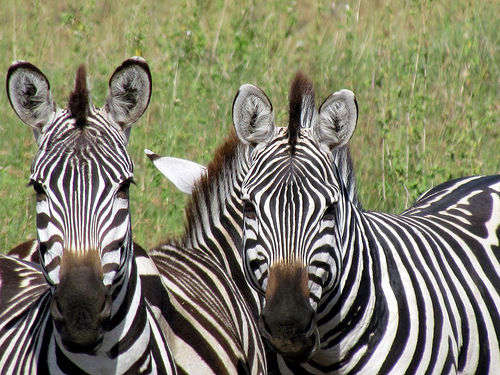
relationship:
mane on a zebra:
[275, 62, 336, 152] [228, 84, 497, 373]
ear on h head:
[228, 80, 282, 147] [228, 76, 371, 363]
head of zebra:
[228, 76, 371, 363] [228, 84, 497, 373]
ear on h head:
[317, 80, 353, 154] [228, 76, 371, 363]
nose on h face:
[257, 267, 318, 337] [233, 136, 342, 350]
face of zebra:
[233, 136, 342, 350] [228, 84, 497, 373]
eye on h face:
[115, 180, 129, 201] [30, 127, 131, 323]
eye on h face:
[28, 176, 53, 206] [30, 127, 131, 323]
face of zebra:
[30, 127, 131, 323] [6, 56, 266, 372]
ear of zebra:
[12, 62, 52, 140] [6, 56, 266, 372]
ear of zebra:
[101, 47, 155, 125] [6, 56, 266, 372]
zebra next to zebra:
[228, 84, 497, 373] [6, 56, 266, 372]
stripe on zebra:
[353, 212, 407, 372] [228, 84, 497, 373]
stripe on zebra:
[361, 206, 437, 373] [228, 84, 497, 373]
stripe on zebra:
[133, 257, 263, 373] [6, 56, 266, 372]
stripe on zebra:
[426, 186, 498, 286] [228, 84, 497, 373]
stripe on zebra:
[299, 206, 379, 320] [228, 84, 497, 373]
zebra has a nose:
[228, 84, 497, 373] [255, 257, 320, 340]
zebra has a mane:
[228, 84, 497, 373] [281, 66, 326, 149]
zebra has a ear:
[6, 56, 266, 372] [104, 52, 160, 126]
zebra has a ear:
[6, 56, 266, 372] [6, 63, 64, 141]